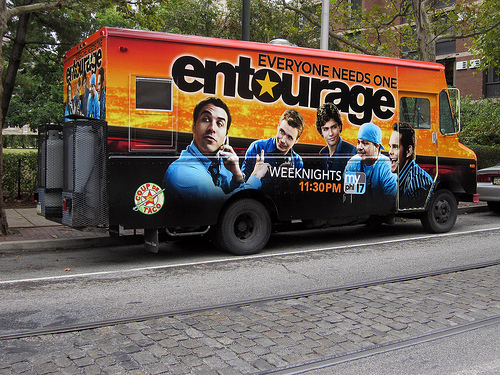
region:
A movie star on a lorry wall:
[168, 83, 245, 222]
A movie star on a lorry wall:
[256, 75, 307, 210]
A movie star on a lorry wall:
[315, 107, 349, 189]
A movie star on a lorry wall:
[344, 123, 396, 210]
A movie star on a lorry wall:
[382, 111, 436, 206]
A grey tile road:
[358, 239, 498, 371]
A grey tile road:
[232, 254, 335, 371]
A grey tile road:
[101, 266, 202, 374]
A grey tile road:
[20, 225, 125, 358]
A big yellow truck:
[74, 3, 490, 243]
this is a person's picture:
[170, 97, 246, 200]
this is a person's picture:
[250, 105, 305, 190]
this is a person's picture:
[316, 102, 352, 177]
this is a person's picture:
[342, 122, 389, 201]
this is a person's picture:
[390, 121, 428, 213]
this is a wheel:
[222, 197, 272, 251]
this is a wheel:
[427, 191, 454, 231]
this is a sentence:
[168, 47, 401, 115]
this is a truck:
[50, 23, 485, 248]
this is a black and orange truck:
[42, 27, 480, 249]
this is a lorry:
[69, 21, 466, 263]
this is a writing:
[173, 53, 280, 93]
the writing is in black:
[189, 60, 237, 82]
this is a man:
[169, 100, 244, 199]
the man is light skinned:
[216, 134, 228, 139]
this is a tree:
[334, 13, 449, 69]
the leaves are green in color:
[23, 60, 61, 119]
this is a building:
[446, 41, 496, 101]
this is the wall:
[455, 71, 485, 96]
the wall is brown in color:
[445, 65, 469, 85]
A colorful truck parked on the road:
[36, 27, 476, 252]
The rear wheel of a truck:
[221, 198, 268, 255]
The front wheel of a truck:
[418, 188, 458, 235]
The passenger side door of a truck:
[393, 85, 438, 210]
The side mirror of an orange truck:
[444, 84, 462, 136]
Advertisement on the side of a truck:
[161, 37, 436, 207]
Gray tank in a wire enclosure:
[66, 113, 106, 228]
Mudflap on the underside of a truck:
[141, 225, 158, 253]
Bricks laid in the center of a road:
[15, 259, 498, 374]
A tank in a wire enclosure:
[36, 121, 64, 215]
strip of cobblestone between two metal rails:
[2, 256, 493, 371]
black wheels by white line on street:
[205, 190, 461, 300]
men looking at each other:
[167, 100, 427, 200]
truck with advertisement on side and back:
[56, 25, 472, 260]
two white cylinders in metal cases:
[35, 116, 105, 228]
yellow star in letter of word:
[161, 52, 391, 118]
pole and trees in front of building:
[301, 0, 496, 95]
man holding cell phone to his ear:
[185, 95, 235, 185]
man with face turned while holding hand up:
[166, 100, 301, 195]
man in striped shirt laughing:
[385, 120, 435, 190]